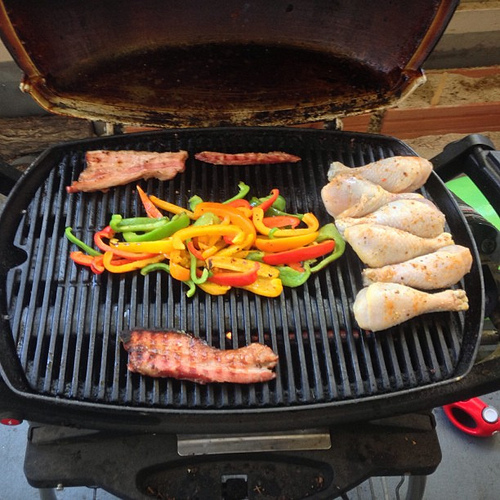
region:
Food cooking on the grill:
[63, 146, 417, 369]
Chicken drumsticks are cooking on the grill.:
[339, 158, 453, 303]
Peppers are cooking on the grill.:
[90, 200, 320, 283]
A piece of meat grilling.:
[113, 296, 270, 386]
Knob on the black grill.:
[193, 456, 286, 497]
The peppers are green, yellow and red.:
[126, 195, 278, 275]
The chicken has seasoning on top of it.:
[358, 177, 430, 281]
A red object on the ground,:
[433, 393, 499, 455]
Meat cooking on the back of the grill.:
[70, 138, 299, 189]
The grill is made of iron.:
[43, 234, 329, 335]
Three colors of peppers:
[126, 212, 306, 289]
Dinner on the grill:
[64, 135, 469, 409]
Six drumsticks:
[353, 148, 463, 352]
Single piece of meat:
[108, 346, 298, 383]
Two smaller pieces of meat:
[82, 135, 314, 194]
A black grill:
[27, 272, 117, 384]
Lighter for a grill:
[468, 390, 497, 445]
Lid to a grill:
[16, 36, 419, 132]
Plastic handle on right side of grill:
[452, 110, 499, 226]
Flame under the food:
[219, 322, 249, 345]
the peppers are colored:
[57, 172, 349, 332]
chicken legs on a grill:
[238, 130, 491, 378]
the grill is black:
[6, 116, 499, 489]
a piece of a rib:
[86, 300, 298, 405]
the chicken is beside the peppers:
[51, 147, 475, 352]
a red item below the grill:
[440, 342, 499, 479]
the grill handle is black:
[412, 107, 497, 232]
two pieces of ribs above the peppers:
[52, 130, 334, 324]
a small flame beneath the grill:
[202, 319, 267, 362]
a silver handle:
[133, 406, 349, 471]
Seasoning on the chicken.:
[333, 172, 440, 311]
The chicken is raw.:
[321, 155, 458, 331]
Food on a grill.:
[56, 141, 455, 395]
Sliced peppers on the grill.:
[71, 193, 328, 295]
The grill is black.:
[21, 117, 477, 494]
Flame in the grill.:
[210, 314, 256, 343]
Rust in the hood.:
[57, 6, 391, 108]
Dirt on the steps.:
[421, 70, 496, 157]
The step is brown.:
[407, 107, 498, 134]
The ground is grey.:
[441, 447, 499, 499]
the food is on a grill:
[66, 146, 464, 392]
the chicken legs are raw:
[324, 152, 471, 334]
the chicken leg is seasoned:
[381, 286, 447, 322]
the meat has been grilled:
[124, 325, 280, 390]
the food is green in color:
[113, 216, 189, 241]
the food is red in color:
[265, 241, 336, 266]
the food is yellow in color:
[114, 238, 184, 256]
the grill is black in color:
[3, 133, 484, 433]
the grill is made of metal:
[8, 136, 492, 436]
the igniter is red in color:
[444, 394, 498, 436]